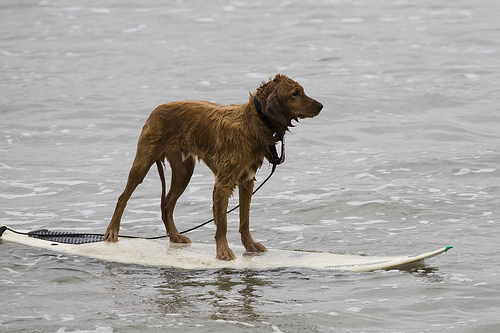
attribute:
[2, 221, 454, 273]
surfboard — long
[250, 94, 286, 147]
dog collar — black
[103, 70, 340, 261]
dog — brown, leg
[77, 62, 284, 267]
dog — wet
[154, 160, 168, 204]
tail — wet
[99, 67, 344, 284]
dog — wet 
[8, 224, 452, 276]
surfboard — white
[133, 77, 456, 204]
dog — wet, brown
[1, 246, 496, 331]
water — calm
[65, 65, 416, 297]
dog —  brown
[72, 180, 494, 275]
surfboard — white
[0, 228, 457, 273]
surfboard — white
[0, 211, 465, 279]
board — surf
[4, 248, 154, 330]
water — smooth